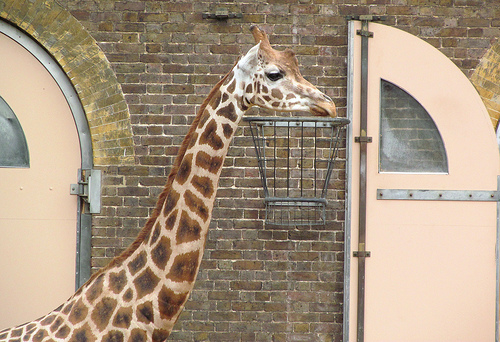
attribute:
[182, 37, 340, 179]
giraffe — standing, tall, brown, white, looking, spotted, huge, black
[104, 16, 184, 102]
wall — brick, old, brown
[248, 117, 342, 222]
basket — gray, metal, high, hanging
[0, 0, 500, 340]
wall — brick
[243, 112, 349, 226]
basket — metal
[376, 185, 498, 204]
metal strip — horizontal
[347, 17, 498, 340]
door — pink, close, open